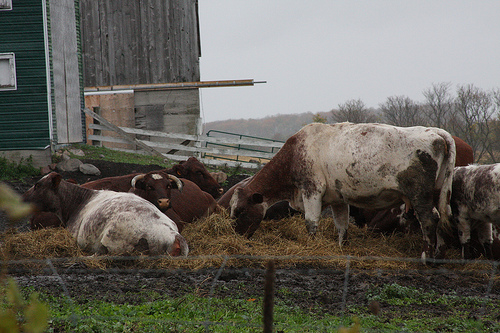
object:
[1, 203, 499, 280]
hay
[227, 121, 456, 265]
cow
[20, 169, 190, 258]
cow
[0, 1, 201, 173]
barn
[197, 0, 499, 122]
sky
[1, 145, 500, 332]
ground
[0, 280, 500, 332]
grass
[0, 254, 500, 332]
fence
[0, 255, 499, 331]
wire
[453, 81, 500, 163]
trees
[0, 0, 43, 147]
green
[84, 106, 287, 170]
fence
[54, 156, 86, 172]
rocks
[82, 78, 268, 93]
long object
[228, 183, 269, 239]
head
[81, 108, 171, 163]
slats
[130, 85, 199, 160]
gate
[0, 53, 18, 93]
window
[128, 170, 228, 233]
cow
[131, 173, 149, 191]
horns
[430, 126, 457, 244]
tail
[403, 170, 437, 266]
hind leg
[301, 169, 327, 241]
front leg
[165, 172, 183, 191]
horn